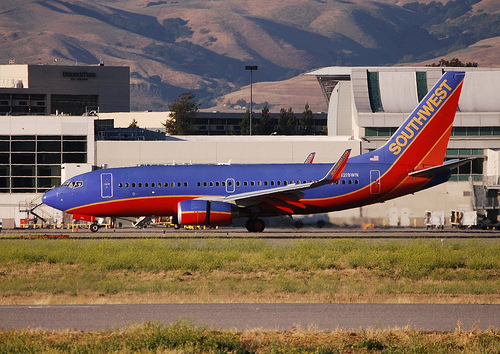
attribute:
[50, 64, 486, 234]
airplane — purple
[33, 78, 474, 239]
airplane — purple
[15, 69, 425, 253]
airplane — red, blue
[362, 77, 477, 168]
letters — written, yellow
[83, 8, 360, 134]
mountain — huge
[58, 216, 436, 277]
tarmac — black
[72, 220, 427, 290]
weeds — overgrown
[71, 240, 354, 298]
dirt — patched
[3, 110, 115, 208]
building — concrete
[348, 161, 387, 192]
exit — emergency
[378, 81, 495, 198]
name — yellow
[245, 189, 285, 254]
wheel — rear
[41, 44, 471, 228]
building — white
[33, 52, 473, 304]
building — white